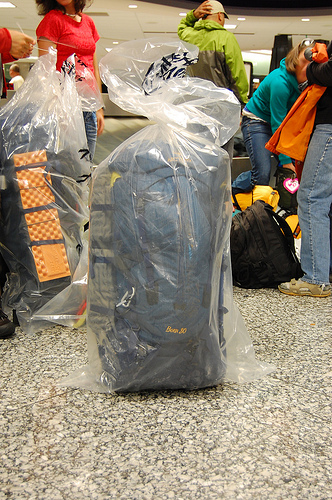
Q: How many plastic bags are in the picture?
A: Two.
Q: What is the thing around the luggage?
A: Plastic bag.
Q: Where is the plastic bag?
A: Around the luggage.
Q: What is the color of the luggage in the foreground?
A: Blue.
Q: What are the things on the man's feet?
A: Shoes.